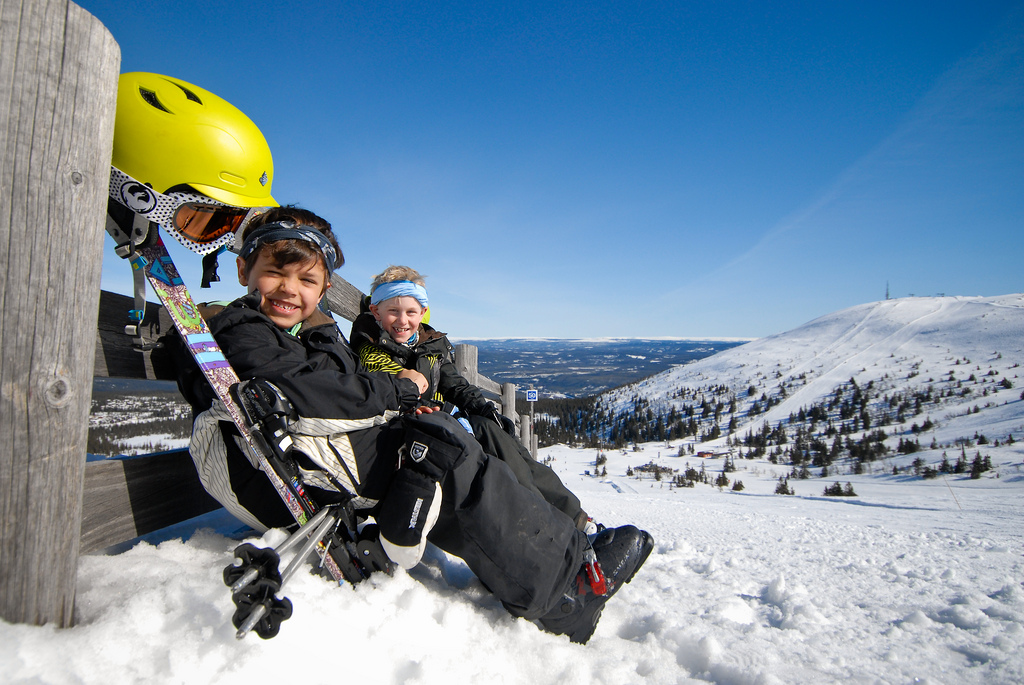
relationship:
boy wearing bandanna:
[161, 202, 654, 651] [255, 215, 338, 282]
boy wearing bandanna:
[345, 260, 604, 578] [376, 268, 426, 357]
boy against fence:
[161, 202, 654, 651] [42, 242, 211, 493]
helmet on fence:
[106, 62, 295, 271] [24, 299, 184, 539]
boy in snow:
[161, 202, 654, 651] [653, 539, 876, 676]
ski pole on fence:
[137, 256, 341, 581] [9, 232, 152, 565]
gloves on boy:
[404, 361, 487, 506] [240, 229, 396, 539]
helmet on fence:
[106, 48, 277, 271] [14, 102, 155, 548]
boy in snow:
[161, 202, 654, 651] [640, 489, 882, 678]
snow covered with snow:
[821, 565, 927, 678] [335, 601, 465, 669]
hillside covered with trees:
[742, 305, 995, 578] [780, 368, 895, 509]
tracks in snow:
[720, 532, 846, 643] [707, 571, 820, 647]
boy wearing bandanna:
[370, 268, 571, 577] [369, 280, 432, 310]